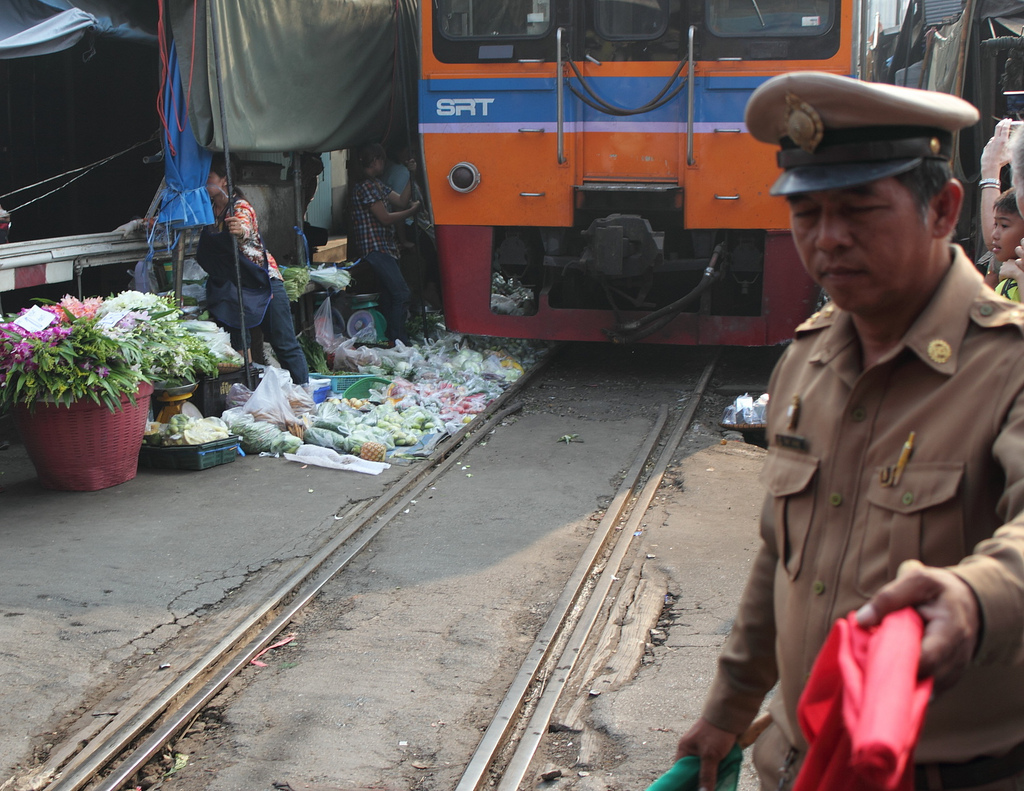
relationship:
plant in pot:
[4, 276, 230, 400] [12, 385, 167, 491]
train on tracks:
[417, 0, 875, 348] [38, 346, 717, 787]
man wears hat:
[673, 71, 1023, 791] [727, 62, 980, 202]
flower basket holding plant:
[16, 378, 151, 490] [0, 280, 236, 404]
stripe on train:
[407, 75, 791, 120] [417, 0, 875, 348]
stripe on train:
[417, 116, 766, 139] [417, 0, 875, 348]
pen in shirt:
[894, 429, 924, 465] [705, 238, 1016, 771]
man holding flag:
[731, 73, 1022, 585] [790, 601, 942, 787]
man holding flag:
[195, 183, 355, 404] [660, 757, 734, 786]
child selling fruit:
[974, 117, 1024, 302] [258, 333, 526, 474]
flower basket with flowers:
[34, 381, 149, 485] [16, 273, 216, 439]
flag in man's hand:
[790, 593, 931, 786] [853, 549, 968, 686]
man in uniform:
[673, 71, 1023, 791] [682, 243, 1020, 760]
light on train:
[451, 161, 480, 198] [417, 0, 875, 348]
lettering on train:
[436, 99, 494, 116] [399, 15, 994, 419]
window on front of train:
[428, 6, 848, 78] [399, 15, 994, 419]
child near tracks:
[971, 169, 1017, 324] [66, 352, 753, 787]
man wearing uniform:
[673, 71, 1023, 791] [736, 75, 1019, 532]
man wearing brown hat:
[673, 71, 1023, 791] [716, 44, 954, 207]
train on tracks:
[399, 15, 994, 419] [341, 363, 653, 610]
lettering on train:
[432, 87, 498, 131] [395, 23, 987, 380]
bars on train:
[501, 238, 741, 293] [399, 15, 994, 419]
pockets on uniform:
[752, 444, 839, 574] [626, 53, 1007, 788]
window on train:
[419, 0, 851, 79] [395, 23, 987, 380]